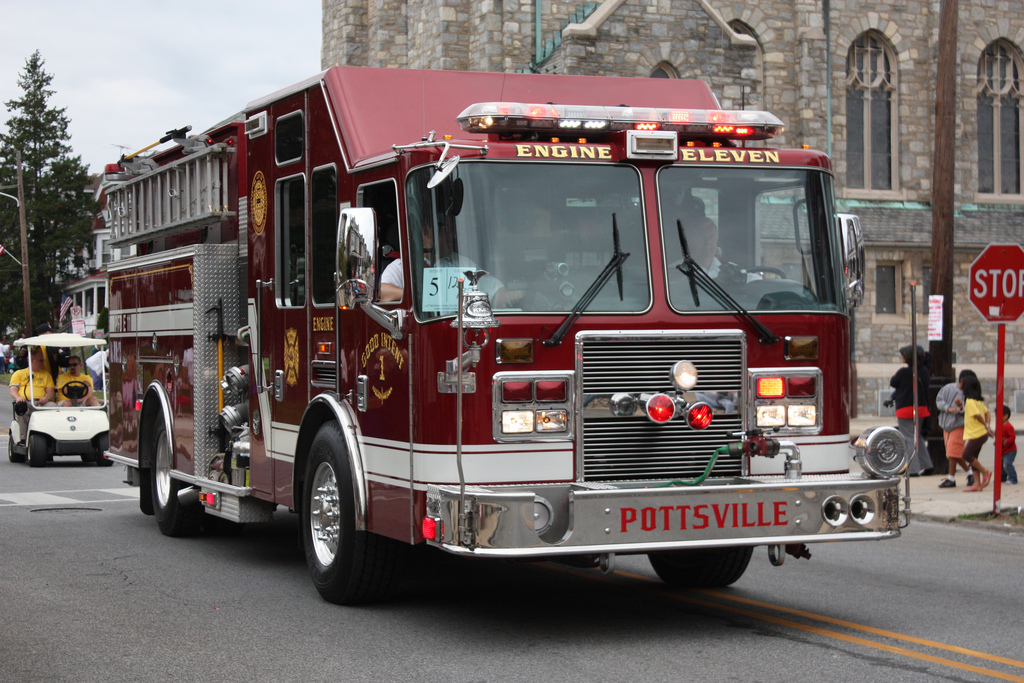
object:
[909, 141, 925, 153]
brick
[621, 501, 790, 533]
pottsville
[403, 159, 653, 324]
window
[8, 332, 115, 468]
golf cart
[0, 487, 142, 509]
crosswalk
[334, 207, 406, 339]
sideview mirror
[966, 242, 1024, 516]
stop sign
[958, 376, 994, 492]
girl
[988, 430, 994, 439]
hand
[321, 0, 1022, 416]
building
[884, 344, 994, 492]
people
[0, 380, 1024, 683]
street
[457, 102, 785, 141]
light bar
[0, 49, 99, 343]
tree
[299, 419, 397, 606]
tire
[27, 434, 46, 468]
tire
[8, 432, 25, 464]
tire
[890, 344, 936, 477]
person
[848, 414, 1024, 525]
sidewalk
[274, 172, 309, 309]
window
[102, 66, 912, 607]
fire engine